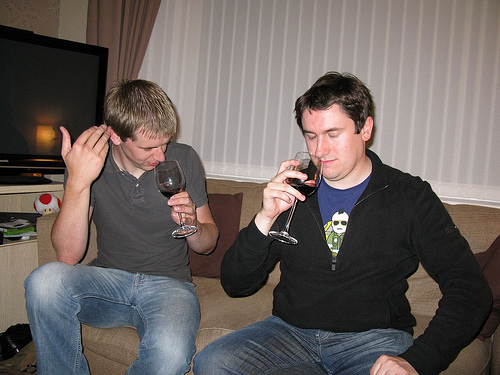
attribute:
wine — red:
[289, 175, 317, 197]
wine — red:
[159, 186, 181, 199]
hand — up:
[57, 122, 110, 183]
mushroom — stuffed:
[32, 192, 62, 216]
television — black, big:
[1, 26, 110, 183]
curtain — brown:
[85, 0, 164, 105]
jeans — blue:
[191, 313, 412, 374]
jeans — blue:
[22, 260, 202, 374]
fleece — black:
[219, 148, 493, 374]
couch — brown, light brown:
[35, 177, 498, 374]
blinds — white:
[134, 1, 499, 203]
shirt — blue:
[314, 172, 370, 273]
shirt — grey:
[64, 137, 208, 285]